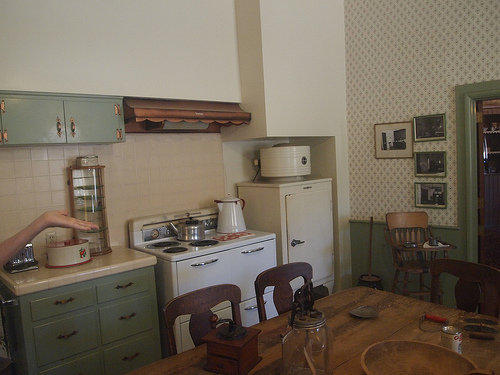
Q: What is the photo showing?
A: It is showing a kitchen.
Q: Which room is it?
A: It is a kitchen.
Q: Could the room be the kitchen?
A: Yes, it is the kitchen.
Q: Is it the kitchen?
A: Yes, it is the kitchen.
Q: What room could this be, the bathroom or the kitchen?
A: It is the kitchen.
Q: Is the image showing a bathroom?
A: No, the picture is showing a kitchen.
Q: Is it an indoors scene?
A: Yes, it is indoors.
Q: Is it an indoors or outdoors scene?
A: It is indoors.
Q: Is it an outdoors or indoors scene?
A: It is indoors.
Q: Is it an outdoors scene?
A: No, it is indoors.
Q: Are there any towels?
A: No, there are no towels.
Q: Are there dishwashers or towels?
A: No, there are no towels or dishwashers.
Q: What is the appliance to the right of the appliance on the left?
A: The appliance is a stove.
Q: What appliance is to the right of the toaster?
A: The appliance is a stove.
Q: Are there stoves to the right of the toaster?
A: Yes, there is a stove to the right of the toaster.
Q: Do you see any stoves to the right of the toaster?
A: Yes, there is a stove to the right of the toaster.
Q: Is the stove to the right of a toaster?
A: Yes, the stove is to the right of a toaster.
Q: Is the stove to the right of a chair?
A: No, the stove is to the right of a toaster.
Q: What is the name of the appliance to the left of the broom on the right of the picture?
A: The appliance is a stove.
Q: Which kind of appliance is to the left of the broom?
A: The appliance is a stove.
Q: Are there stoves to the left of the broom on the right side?
A: Yes, there is a stove to the left of the broom.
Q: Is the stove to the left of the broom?
A: Yes, the stove is to the left of the broom.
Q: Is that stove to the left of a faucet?
A: No, the stove is to the left of the broom.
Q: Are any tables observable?
A: Yes, there is a table.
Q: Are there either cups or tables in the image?
A: Yes, there is a table.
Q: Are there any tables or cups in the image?
A: Yes, there is a table.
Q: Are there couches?
A: No, there are no couches.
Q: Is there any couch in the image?
A: No, there are no couches.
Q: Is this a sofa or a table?
A: This is a table.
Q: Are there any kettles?
A: Yes, there is a kettle.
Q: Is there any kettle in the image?
A: Yes, there is a kettle.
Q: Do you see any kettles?
A: Yes, there is a kettle.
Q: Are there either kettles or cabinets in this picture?
A: Yes, there is a kettle.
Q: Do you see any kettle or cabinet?
A: Yes, there is a kettle.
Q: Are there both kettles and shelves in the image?
A: No, there is a kettle but no shelves.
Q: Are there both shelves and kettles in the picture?
A: No, there is a kettle but no shelves.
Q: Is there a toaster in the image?
A: Yes, there is a toaster.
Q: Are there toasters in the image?
A: Yes, there is a toaster.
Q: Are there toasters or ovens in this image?
A: Yes, there is a toaster.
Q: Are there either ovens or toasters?
A: Yes, there is a toaster.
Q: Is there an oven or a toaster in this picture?
A: Yes, there is a toaster.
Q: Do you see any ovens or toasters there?
A: Yes, there is a toaster.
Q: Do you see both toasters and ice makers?
A: No, there is a toaster but no ice makers.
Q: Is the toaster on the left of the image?
A: Yes, the toaster is on the left of the image.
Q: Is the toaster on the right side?
A: No, the toaster is on the left of the image.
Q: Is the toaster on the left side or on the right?
A: The toaster is on the left of the image.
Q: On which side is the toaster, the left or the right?
A: The toaster is on the left of the image.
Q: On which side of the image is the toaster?
A: The toaster is on the left of the image.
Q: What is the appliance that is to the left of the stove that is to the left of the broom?
A: The appliance is a toaster.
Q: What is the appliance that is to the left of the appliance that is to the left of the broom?
A: The appliance is a toaster.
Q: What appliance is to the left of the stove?
A: The appliance is a toaster.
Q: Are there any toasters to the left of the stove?
A: Yes, there is a toaster to the left of the stove.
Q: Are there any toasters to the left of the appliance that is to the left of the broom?
A: Yes, there is a toaster to the left of the stove.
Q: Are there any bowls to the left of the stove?
A: No, there is a toaster to the left of the stove.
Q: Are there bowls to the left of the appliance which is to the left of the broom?
A: No, there is a toaster to the left of the stove.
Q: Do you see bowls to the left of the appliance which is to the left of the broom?
A: No, there is a toaster to the left of the stove.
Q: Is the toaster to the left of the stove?
A: Yes, the toaster is to the left of the stove.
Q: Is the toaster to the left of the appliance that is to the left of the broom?
A: Yes, the toaster is to the left of the stove.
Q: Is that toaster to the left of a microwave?
A: No, the toaster is to the left of the stove.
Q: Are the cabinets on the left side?
A: Yes, the cabinets are on the left of the image.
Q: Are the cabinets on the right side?
A: No, the cabinets are on the left of the image.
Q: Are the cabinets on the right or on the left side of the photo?
A: The cabinets are on the left of the image.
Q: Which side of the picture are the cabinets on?
A: The cabinets are on the left of the image.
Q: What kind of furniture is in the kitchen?
A: The pieces of furniture are cabinets.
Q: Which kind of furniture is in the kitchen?
A: The pieces of furniture are cabinets.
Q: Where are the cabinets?
A: The cabinets are in the kitchen.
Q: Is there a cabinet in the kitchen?
A: Yes, there are cabinets in the kitchen.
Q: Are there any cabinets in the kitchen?
A: Yes, there are cabinets in the kitchen.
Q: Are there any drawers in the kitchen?
A: No, there are cabinets in the kitchen.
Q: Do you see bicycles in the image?
A: No, there are no bicycles.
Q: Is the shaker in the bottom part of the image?
A: Yes, the shaker is in the bottom of the image.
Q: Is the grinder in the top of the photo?
A: No, the grinder is in the bottom of the image.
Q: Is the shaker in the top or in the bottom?
A: The shaker is in the bottom of the image.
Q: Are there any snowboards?
A: No, there are no snowboards.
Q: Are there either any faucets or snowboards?
A: No, there are no snowboards or faucets.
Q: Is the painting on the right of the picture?
A: Yes, the painting is on the right of the image.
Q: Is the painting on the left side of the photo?
A: No, the painting is on the right of the image.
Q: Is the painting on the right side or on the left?
A: The painting is on the right of the image.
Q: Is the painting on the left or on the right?
A: The painting is on the right of the image.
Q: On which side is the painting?
A: The painting is on the right of the image.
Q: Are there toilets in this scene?
A: No, there are no toilets.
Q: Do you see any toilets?
A: No, there are no toilets.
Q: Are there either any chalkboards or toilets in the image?
A: No, there are no toilets or chalkboards.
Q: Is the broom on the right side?
A: Yes, the broom is on the right of the image.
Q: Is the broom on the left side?
A: No, the broom is on the right of the image.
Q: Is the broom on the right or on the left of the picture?
A: The broom is on the right of the image.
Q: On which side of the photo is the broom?
A: The broom is on the right of the image.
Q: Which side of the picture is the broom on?
A: The broom is on the right of the image.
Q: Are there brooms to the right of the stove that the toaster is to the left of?
A: Yes, there is a broom to the right of the stove.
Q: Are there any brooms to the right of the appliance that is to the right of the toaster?
A: Yes, there is a broom to the right of the stove.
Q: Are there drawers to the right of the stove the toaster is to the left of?
A: No, there is a broom to the right of the stove.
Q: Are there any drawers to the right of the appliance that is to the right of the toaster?
A: No, there is a broom to the right of the stove.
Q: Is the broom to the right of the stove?
A: Yes, the broom is to the right of the stove.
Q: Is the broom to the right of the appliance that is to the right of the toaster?
A: Yes, the broom is to the right of the stove.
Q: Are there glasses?
A: No, there are no glasses.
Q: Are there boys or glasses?
A: No, there are no glasses or boys.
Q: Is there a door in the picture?
A: Yes, there is a door.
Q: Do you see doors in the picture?
A: Yes, there is a door.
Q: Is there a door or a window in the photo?
A: Yes, there is a door.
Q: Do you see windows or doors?
A: Yes, there is a door.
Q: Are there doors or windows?
A: Yes, there is a door.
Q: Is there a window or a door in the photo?
A: Yes, there is a door.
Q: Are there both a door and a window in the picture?
A: No, there is a door but no windows.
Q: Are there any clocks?
A: No, there are no clocks.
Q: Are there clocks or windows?
A: No, there are no clocks or windows.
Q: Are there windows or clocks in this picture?
A: No, there are no clocks or windows.